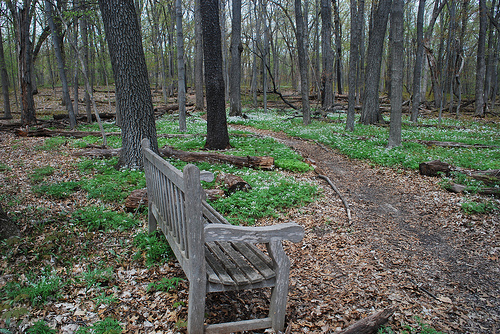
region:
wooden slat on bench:
[177, 186, 186, 248]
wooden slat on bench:
[174, 187, 182, 254]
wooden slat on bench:
[168, 178, 180, 247]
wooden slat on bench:
[236, 239, 268, 277]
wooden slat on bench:
[220, 240, 260, 282]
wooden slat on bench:
[205, 241, 240, 278]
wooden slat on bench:
[200, 247, 230, 287]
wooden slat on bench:
[198, 260, 218, 286]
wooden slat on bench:
[203, 315, 268, 331]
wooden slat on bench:
[178, 159, 208, 331]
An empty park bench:
[120, 128, 307, 329]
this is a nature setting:
[11, 18, 468, 315]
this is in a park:
[14, 22, 389, 234]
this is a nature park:
[13, 34, 440, 271]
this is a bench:
[139, 116, 306, 312]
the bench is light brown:
[156, 189, 281, 331]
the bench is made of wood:
[134, 164, 264, 329]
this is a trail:
[291, 150, 473, 330]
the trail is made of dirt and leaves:
[326, 154, 483, 326]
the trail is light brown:
[316, 154, 481, 315]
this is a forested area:
[59, 37, 477, 174]